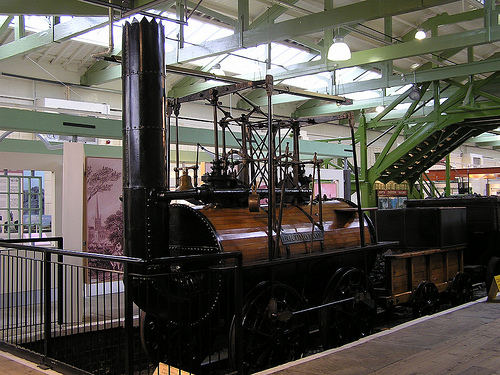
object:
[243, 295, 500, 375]
pathway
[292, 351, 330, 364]
lines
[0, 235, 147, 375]
rail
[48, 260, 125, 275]
rod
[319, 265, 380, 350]
engine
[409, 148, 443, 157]
steps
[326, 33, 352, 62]
lights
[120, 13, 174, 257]
chimney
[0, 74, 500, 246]
wall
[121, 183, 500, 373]
train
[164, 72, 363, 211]
shed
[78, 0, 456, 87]
bar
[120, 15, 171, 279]
pipe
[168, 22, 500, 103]
beams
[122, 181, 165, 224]
metal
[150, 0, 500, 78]
ceiling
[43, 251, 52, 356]
poles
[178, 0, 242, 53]
windows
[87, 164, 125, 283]
picture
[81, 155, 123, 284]
frame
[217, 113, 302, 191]
fence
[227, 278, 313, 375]
wheel